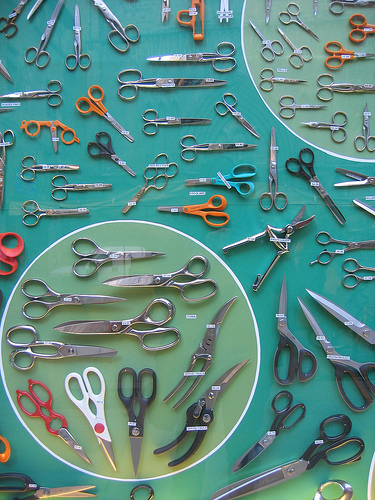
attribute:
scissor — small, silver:
[174, 130, 259, 163]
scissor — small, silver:
[282, 143, 350, 230]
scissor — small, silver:
[113, 64, 230, 106]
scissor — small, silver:
[87, 0, 143, 56]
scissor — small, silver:
[81, 126, 140, 179]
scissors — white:
[64, 364, 117, 471]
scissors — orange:
[88, 131, 136, 177]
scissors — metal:
[47, 173, 113, 202]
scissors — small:
[14, 113, 87, 159]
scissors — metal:
[18, 154, 83, 182]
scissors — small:
[212, 90, 262, 141]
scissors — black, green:
[72, 83, 135, 145]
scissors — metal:
[104, 256, 218, 305]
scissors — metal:
[70, 237, 167, 279]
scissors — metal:
[259, 129, 287, 213]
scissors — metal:
[116, 67, 226, 102]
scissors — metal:
[21, 279, 128, 321]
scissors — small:
[49, 172, 112, 204]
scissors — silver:
[19, 152, 80, 185]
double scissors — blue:
[120, 151, 179, 216]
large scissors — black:
[212, 408, 365, 498]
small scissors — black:
[228, 385, 306, 472]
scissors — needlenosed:
[299, 112, 350, 140]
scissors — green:
[156, 195, 234, 225]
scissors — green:
[179, 132, 258, 160]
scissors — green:
[285, 147, 348, 225]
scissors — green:
[246, 20, 285, 66]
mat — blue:
[3, 1, 366, 498]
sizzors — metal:
[259, 127, 288, 213]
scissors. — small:
[242, 19, 314, 90]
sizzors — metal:
[47, 171, 113, 202]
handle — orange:
[60, 368, 109, 421]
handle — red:
[63, 362, 109, 414]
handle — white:
[66, 360, 111, 409]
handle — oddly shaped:
[17, 374, 64, 429]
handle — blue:
[209, 151, 262, 208]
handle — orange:
[196, 177, 227, 239]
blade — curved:
[204, 299, 242, 341]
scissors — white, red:
[20, 378, 90, 470]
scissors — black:
[112, 359, 159, 476]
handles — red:
[9, 381, 56, 419]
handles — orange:
[186, 188, 227, 225]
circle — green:
[17, 205, 260, 494]